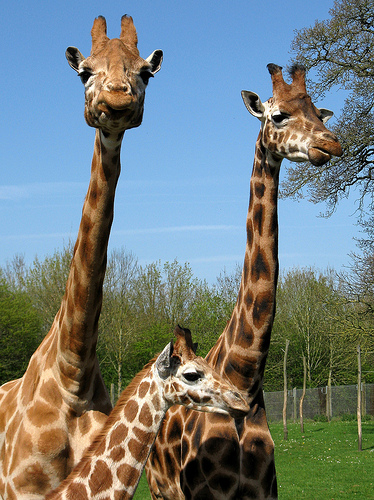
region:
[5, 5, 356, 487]
Three giraffe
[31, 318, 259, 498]
Very young giraffe with two adult giraffe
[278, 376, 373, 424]
Fence in between some trees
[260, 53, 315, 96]
Giraffe ossicones with black tips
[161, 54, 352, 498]
Adult giraffe with black centers in orange markings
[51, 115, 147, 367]
Long neck of a giraffe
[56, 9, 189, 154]
Giraffe with a snarl on its face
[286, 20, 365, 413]
Trees with green leaves against a clear blue sky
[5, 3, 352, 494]
Trio of giraffes hanging together on a clear day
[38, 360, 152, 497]
Orange-Brown ruff on the neck of a giraffe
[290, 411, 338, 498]
the grass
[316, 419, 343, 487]
the grass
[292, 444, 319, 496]
the grass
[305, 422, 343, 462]
the grass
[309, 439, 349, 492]
the grass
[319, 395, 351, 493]
the grass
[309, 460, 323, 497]
the grass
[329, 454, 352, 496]
the grass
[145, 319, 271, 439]
a giraffe looking off towards it's left.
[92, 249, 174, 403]
a tree with green leaves.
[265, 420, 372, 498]
a lush green field of grass.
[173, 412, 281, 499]
the front of a giraffe.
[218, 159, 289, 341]
a giraffe's long neck.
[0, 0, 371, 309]
a clear blue sky.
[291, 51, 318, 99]
a horn on a giraffe.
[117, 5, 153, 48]
a horn on a giraffe's head.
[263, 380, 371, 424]
a chain link fence.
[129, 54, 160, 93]
left eye of a giraffe.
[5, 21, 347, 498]
three giraffes in photos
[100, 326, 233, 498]
small giraffe looking right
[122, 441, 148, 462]
brown spot on giraffe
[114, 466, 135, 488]
brown spot on giraffe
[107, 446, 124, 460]
brown spot on giraffe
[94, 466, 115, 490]
brown spot on giraffe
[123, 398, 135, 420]
brown spot on giraffe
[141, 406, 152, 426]
brown spot on giraffe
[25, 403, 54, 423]
brown spot on giraffe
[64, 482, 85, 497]
brown spot on giraffe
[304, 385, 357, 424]
Chain-link retaining fence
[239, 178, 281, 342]
Long neck of a giraffe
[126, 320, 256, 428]
Young giraffe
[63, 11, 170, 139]
Giraffe looking into the camera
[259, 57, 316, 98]
Horns on the head of a giraffe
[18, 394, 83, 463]
Brown spots on a giraffe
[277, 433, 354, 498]
Green grassy field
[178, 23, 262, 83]
Light blue summer sky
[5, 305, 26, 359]
Foliage of trees in the background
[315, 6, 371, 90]
Branches of a tree